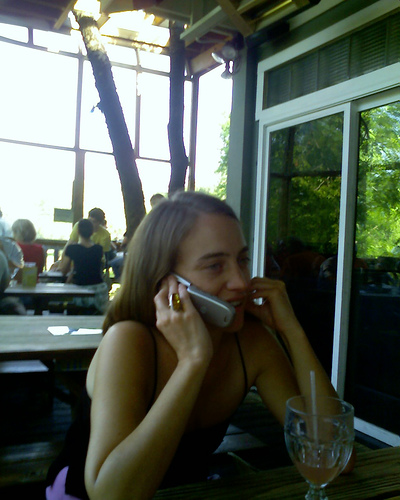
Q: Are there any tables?
A: Yes, there is a table.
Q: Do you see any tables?
A: Yes, there is a table.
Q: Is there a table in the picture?
A: Yes, there is a table.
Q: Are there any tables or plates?
A: Yes, there is a table.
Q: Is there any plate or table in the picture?
A: Yes, there is a table.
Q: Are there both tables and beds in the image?
A: No, there is a table but no beds.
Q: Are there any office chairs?
A: No, there are no office chairs.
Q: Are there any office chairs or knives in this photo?
A: No, there are no office chairs or knives.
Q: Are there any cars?
A: No, there are no cars.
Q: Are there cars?
A: No, there are no cars.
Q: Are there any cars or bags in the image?
A: No, there are no cars or bags.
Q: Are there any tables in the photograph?
A: Yes, there is a table.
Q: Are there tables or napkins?
A: Yes, there is a table.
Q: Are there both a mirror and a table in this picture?
A: No, there is a table but no mirrors.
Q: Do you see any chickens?
A: No, there are no chickens.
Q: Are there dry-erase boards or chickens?
A: No, there are no chickens or dry-erase boards.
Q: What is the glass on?
A: The glass is on the table.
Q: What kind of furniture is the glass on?
A: The glass is on the table.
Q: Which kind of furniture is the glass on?
A: The glass is on the table.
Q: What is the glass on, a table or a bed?
A: The glass is on a table.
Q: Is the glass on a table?
A: Yes, the glass is on a table.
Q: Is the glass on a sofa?
A: No, the glass is on a table.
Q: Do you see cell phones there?
A: Yes, there is a cell phone.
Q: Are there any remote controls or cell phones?
A: Yes, there is a cell phone.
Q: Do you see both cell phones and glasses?
A: Yes, there are both a cell phone and glasses.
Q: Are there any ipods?
A: No, there are no ipods.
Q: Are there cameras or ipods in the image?
A: No, there are no ipods or cameras.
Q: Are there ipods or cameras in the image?
A: No, there are no ipods or cameras.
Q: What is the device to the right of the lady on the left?
A: The device is a cell phone.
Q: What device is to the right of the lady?
A: The device is a cell phone.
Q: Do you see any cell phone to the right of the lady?
A: Yes, there is a cell phone to the right of the lady.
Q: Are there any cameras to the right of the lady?
A: No, there is a cell phone to the right of the lady.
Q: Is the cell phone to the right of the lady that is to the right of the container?
A: Yes, the cell phone is to the right of the lady.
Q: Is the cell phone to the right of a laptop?
A: No, the cell phone is to the right of the lady.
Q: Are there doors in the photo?
A: Yes, there is a door.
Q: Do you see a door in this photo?
A: Yes, there is a door.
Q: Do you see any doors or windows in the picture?
A: Yes, there is a door.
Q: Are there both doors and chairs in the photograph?
A: No, there is a door but no chairs.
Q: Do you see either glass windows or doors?
A: Yes, there is a glass door.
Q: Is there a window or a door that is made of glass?
A: Yes, the door is made of glass.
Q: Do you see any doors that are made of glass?
A: Yes, there is a door that is made of glass.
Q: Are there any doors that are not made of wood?
A: Yes, there is a door that is made of glass.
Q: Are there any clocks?
A: No, there are no clocks.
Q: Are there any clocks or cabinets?
A: No, there are no clocks or cabinets.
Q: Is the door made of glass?
A: Yes, the door is made of glass.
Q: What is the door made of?
A: The door is made of glass.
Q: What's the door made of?
A: The door is made of glass.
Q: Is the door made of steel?
A: No, the door is made of glass.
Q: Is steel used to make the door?
A: No, the door is made of glass.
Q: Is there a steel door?
A: No, there is a door but it is made of glass.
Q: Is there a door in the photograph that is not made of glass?
A: No, there is a door but it is made of glass.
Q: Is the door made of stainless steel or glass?
A: The door is made of glass.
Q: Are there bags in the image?
A: No, there are no bags.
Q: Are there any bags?
A: No, there are no bags.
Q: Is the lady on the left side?
A: Yes, the lady is on the left of the image.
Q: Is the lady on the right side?
A: No, the lady is on the left of the image.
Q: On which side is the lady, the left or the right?
A: The lady is on the left of the image.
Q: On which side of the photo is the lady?
A: The lady is on the left of the image.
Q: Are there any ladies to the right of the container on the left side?
A: Yes, there is a lady to the right of the container.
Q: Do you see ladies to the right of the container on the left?
A: Yes, there is a lady to the right of the container.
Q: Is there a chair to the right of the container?
A: No, there is a lady to the right of the container.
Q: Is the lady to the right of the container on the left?
A: Yes, the lady is to the right of the container.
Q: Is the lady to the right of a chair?
A: No, the lady is to the right of the container.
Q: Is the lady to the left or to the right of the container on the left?
A: The lady is to the right of the container.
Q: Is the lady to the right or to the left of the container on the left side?
A: The lady is to the right of the container.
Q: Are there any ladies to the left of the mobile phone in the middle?
A: Yes, there is a lady to the left of the cellphone.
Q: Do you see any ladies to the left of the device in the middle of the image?
A: Yes, there is a lady to the left of the cellphone.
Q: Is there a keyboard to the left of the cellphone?
A: No, there is a lady to the left of the cellphone.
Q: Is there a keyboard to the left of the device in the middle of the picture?
A: No, there is a lady to the left of the cellphone.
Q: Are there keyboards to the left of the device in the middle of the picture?
A: No, there is a lady to the left of the cellphone.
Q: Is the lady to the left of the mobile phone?
A: Yes, the lady is to the left of the mobile phone.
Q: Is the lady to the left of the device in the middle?
A: Yes, the lady is to the left of the mobile phone.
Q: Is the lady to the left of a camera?
A: No, the lady is to the left of the mobile phone.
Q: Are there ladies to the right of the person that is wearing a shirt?
A: Yes, there is a lady to the right of the person.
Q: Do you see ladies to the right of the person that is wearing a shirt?
A: Yes, there is a lady to the right of the person.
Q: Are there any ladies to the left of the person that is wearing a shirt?
A: No, the lady is to the right of the person.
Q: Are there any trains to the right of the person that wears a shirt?
A: No, there is a lady to the right of the person.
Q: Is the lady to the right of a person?
A: Yes, the lady is to the right of a person.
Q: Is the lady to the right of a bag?
A: No, the lady is to the right of a person.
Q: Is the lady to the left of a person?
A: No, the lady is to the right of a person.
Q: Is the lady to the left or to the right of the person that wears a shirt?
A: The lady is to the right of the person.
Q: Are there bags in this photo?
A: No, there are no bags.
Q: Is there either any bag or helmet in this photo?
A: No, there are no bags or helmets.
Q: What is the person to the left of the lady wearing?
A: The person is wearing a shirt.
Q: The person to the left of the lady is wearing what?
A: The person is wearing a shirt.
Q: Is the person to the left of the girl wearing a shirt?
A: Yes, the person is wearing a shirt.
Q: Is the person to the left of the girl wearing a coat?
A: No, the person is wearing a shirt.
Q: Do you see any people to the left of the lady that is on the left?
A: Yes, there is a person to the left of the lady.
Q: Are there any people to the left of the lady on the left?
A: Yes, there is a person to the left of the lady.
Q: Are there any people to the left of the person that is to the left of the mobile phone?
A: Yes, there is a person to the left of the lady.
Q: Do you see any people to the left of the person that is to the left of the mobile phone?
A: Yes, there is a person to the left of the lady.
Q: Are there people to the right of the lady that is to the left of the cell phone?
A: No, the person is to the left of the lady.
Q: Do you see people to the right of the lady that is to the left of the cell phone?
A: No, the person is to the left of the lady.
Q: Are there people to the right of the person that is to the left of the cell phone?
A: No, the person is to the left of the lady.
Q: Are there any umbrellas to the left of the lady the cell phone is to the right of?
A: No, there is a person to the left of the lady.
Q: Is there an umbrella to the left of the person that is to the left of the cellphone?
A: No, there is a person to the left of the lady.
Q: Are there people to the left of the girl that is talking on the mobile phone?
A: Yes, there is a person to the left of the girl.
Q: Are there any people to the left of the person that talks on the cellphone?
A: Yes, there is a person to the left of the girl.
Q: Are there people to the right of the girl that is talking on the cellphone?
A: No, the person is to the left of the girl.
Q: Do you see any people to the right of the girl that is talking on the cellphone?
A: No, the person is to the left of the girl.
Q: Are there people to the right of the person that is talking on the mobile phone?
A: No, the person is to the left of the girl.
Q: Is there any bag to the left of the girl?
A: No, there is a person to the left of the girl.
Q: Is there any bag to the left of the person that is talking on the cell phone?
A: No, there is a person to the left of the girl.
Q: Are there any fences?
A: No, there are no fences.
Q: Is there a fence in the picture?
A: No, there are no fences.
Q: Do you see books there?
A: No, there are no books.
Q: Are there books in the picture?
A: No, there are no books.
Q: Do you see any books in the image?
A: No, there are no books.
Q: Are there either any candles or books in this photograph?
A: No, there are no books or candles.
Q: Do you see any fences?
A: No, there are no fences.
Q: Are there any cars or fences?
A: No, there are no fences or cars.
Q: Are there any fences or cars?
A: No, there are no fences or cars.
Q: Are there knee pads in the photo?
A: No, there are no knee pads.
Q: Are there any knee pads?
A: No, there are no knee pads.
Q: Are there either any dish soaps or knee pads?
A: No, there are no knee pads or dish soaps.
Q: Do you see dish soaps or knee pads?
A: No, there are no knee pads or dish soaps.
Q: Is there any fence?
A: No, there are no fences.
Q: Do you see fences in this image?
A: No, there are no fences.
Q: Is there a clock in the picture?
A: No, there are no clocks.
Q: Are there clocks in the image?
A: No, there are no clocks.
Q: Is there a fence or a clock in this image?
A: No, there are no clocks or fences.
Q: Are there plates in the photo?
A: No, there are no plates.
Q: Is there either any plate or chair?
A: No, there are no plates or chairs.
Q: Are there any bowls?
A: No, there are no bowls.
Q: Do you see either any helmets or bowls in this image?
A: No, there are no bowls or helmets.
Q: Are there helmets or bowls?
A: No, there are no bowls or helmets.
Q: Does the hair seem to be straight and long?
A: Yes, the hair is straight and long.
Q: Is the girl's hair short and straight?
A: No, the hair is straight but long.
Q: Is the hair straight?
A: Yes, the hair is straight.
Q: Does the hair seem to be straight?
A: Yes, the hair is straight.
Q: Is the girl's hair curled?
A: No, the hair is straight.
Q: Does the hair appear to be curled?
A: No, the hair is straight.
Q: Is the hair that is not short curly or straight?
A: The hair is straight.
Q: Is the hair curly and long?
A: No, the hair is long but straight.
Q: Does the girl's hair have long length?
A: Yes, the hair is long.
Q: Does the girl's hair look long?
A: Yes, the hair is long.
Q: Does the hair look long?
A: Yes, the hair is long.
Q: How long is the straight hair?
A: The hair is long.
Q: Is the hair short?
A: No, the hair is long.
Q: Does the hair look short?
A: No, the hair is long.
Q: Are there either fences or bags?
A: No, there are no bags or fences.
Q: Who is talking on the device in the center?
A: The girl is talking on the cell phone.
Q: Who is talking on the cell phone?
A: The girl is talking on the cell phone.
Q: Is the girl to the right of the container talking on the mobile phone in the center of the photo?
A: Yes, the girl is talking on the cell phone.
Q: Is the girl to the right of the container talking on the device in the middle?
A: Yes, the girl is talking on the cell phone.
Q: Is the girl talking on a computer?
A: No, the girl is talking on the cell phone.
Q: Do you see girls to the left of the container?
A: No, the girl is to the right of the container.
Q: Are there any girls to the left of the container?
A: No, the girl is to the right of the container.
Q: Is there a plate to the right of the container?
A: No, there is a girl to the right of the container.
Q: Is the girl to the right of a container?
A: Yes, the girl is to the right of a container.